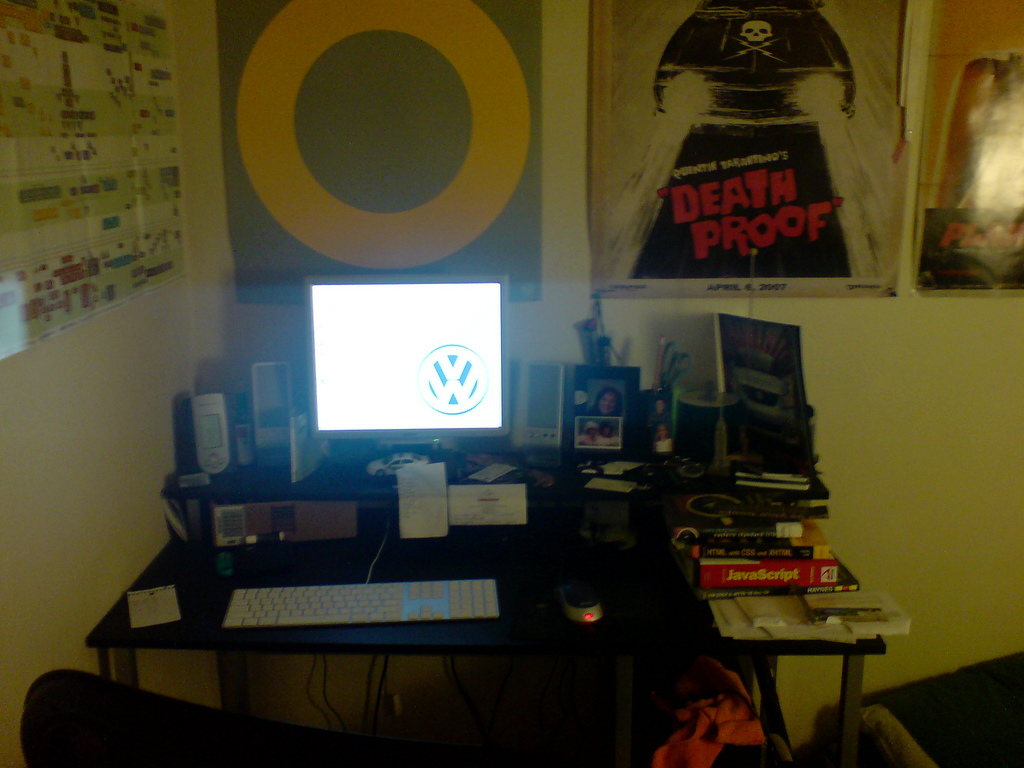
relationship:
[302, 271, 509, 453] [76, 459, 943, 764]
monitor on desk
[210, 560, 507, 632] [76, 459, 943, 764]
keyboard on desk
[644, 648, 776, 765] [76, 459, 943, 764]
bag under desk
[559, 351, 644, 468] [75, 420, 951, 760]
picture frame on desk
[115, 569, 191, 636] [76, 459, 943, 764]
notepad on desk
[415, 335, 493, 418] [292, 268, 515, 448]
logo on monitor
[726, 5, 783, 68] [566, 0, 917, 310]
skull on poster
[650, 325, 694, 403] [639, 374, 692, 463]
scissors in container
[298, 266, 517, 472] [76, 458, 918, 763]
monitor on desk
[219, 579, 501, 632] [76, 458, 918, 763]
keyboard on desk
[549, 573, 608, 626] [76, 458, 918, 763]
mouse on desk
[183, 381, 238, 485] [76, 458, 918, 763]
speaker on desk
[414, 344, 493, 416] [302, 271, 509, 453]
logo on monitor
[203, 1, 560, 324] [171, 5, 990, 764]
poster on wall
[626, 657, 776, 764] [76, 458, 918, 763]
cloth under desk